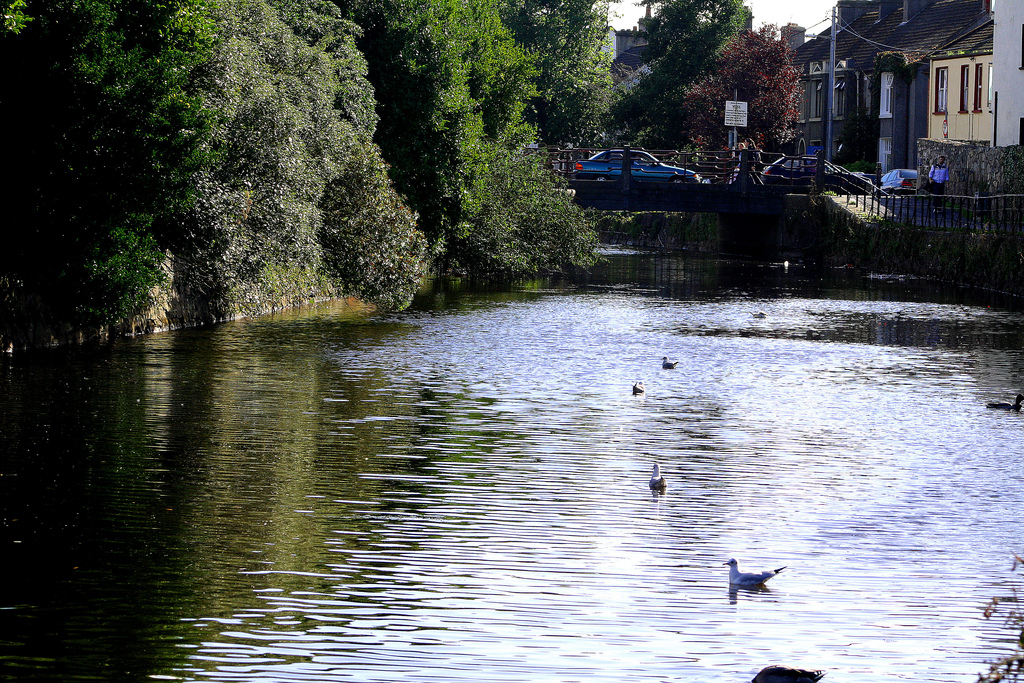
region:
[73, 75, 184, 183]
a tree that is green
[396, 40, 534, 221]
a tree that is dark green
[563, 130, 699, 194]
a car that is blue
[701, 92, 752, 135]
a sign that is white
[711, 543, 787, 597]
a bird thats in the water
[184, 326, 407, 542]
the reflection of some trees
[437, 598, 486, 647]
ripples in the water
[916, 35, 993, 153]
a building that is tan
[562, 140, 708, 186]
blue car next to gate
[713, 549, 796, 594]
bird floating on water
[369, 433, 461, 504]
ripples on surface of water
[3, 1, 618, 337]
green foliage bordering water on the left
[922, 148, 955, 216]
person in white shirt walking along stone wall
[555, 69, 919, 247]
cars next to the water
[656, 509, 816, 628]
bird in the water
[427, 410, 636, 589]
light hitting the water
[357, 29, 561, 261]
leaves on the tree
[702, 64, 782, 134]
sign near the cars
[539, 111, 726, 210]
blue car above water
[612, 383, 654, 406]
bird on the water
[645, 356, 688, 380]
bird on the water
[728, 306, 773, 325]
bird on the water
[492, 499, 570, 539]
ripple on the water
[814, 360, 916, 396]
ripple on the water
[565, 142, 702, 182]
blue car next to fence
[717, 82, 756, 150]
sign on sign pole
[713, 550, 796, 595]
white bird swimming in water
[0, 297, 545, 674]
black shadow on side of water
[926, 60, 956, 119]
window on side of house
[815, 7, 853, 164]
silver electrical pole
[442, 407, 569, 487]
ripples on surface of water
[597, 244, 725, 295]
shadow of fence in water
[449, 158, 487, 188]
green leaves on the tree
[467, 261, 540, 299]
green leaves on the tree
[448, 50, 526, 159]
green leaves on the tree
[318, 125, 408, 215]
green leaves on the tree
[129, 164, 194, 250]
green leaves on the tree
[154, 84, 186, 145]
green leaves on the tree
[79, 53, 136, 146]
green leaves on the tree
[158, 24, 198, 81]
green leaves on the tree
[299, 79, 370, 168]
green leaves on the tree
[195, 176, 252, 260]
green leaves on the tree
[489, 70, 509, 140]
green leaves on the tree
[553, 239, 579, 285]
green leaves on the tree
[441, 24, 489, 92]
green leaves on the tree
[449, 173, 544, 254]
green leaves on the tree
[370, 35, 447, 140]
green leaves on the tree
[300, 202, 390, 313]
green leaves on the tree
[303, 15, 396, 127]
green leaves on the tree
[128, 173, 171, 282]
green leaves on the tree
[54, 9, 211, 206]
green leaves on the tree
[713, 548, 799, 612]
Bird in the water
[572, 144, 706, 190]
Car on a bridge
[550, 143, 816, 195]
Fence made of metal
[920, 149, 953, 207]
Man walking on sidewalk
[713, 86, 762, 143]
Sign on a post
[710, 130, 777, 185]
People walking on bridge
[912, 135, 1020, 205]
Wall made of stone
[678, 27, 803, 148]
Tree with red leaves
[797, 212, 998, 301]
Moss on the stones